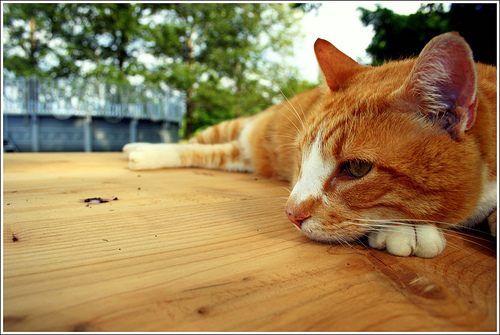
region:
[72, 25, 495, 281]
Orange and white adult cat laying on wooden table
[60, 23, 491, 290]
orange and white adult cat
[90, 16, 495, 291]
orange and white adult cat laying down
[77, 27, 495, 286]
Orange and white cat with yellow eyes laying on table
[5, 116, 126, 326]
Light colored wooden table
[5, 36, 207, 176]
Blue and white above ground pool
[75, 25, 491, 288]
orange cat with white stripes and white feet laying on picnic table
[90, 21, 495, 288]
Resting cat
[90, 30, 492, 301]
Fat orange and white cat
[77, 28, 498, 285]
Big orange and white cat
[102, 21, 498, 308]
A cat laying on a table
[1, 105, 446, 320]
The table is made of wood.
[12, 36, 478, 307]
The cat and the table are outside.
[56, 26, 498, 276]
The cat is yellow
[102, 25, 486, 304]
The cat is awake.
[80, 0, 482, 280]
The cat has white feet.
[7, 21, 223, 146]
A building stands in the distance.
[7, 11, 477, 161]
Shade trees are all around.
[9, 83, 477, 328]
The table is knotty pine.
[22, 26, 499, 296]
The cat has stripes.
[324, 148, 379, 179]
green cat eye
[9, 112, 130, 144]
an above ground pool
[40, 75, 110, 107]
fence around the pool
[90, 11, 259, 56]
green trees above the pool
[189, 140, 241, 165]
white ans orange stripes on the cat leg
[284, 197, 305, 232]
pink nose on the cat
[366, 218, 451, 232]
white whiskers on the cat mouth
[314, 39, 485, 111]
ears on a head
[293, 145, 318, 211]
white spot on a cat face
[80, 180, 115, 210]
black debris on the deck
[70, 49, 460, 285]
orange cat on table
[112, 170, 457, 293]
orange cat on wooden table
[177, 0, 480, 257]
cat in on table outside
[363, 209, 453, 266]
cat has white paw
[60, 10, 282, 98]
green trees in background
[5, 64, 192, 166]
above ground pool in distance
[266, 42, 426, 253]
cat is not looking at the camera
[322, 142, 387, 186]
cat has green eye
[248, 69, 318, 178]
cat has white whiskers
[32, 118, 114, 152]
bottom half of pool is blue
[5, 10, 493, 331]
Exterior shot, daytime.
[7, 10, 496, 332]
Outdoor view, showing domestic animal in residential area.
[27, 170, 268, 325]
Light, pine wood with knots and grain markings.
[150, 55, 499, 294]
Resting, orange and white cat.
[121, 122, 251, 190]
Striped cat legs with white foot.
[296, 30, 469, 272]
Left-facing left profile of reclining cat.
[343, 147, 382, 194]
Cat's green eye.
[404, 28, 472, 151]
White hair, in pink interior of cat ear.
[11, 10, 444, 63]
Pale sky and tall, green vegetation.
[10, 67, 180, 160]
Blue, outdoor structure, possibly pool.